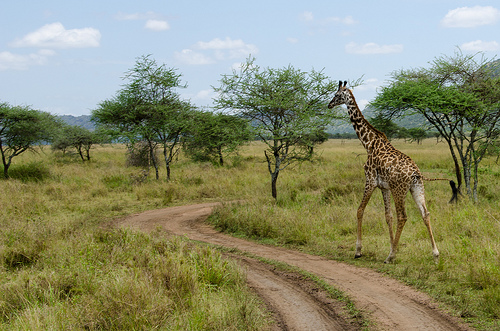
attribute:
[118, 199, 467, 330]
road — dirt, turning right, curved, brown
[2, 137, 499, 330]
field — green, brown, grassy, weedy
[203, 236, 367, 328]
median — grass, grassy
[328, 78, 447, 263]
giraffe — outdoors, running, brown, white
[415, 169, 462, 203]
tail — extended, up, brown, black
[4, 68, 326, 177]
trees — green, thorny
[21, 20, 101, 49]
cloud — white, fluffy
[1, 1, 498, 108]
sky — blue, cloudy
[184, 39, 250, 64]
cloud — fluffy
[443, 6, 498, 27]
cloud — fluffy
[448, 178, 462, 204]
hair — black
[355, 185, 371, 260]
leg — spindly, spotted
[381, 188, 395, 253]
leg — spindly, spotted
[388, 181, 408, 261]
leg — spindly, spotted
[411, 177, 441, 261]
leg — spindly, extended, spotted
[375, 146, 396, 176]
spots — brown, white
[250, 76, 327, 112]
leaves — green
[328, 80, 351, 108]
head — brown, white